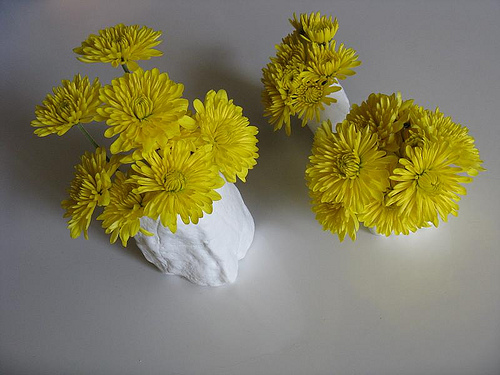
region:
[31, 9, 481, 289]
three vases with yellow bouquets of flowers in each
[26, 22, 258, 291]
largest white vase with yellow flowers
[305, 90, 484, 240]
medium sized white vase with yellow flowers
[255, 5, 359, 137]
smallest white vase with yellow flowers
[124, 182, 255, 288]
white vase for flowers with textured sides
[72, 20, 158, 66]
single yellow flower with a green stem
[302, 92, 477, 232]
several yellow flowers in a bunch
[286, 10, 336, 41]
partially wilted single yellow flower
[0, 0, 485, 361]
gray display table holding three flower vases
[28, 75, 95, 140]
single yellow flower in a larger bunch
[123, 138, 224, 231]
The flower is yellow.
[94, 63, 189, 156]
The flower is yellow.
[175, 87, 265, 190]
The flower is yellow.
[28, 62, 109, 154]
The flower is yellow.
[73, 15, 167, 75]
The flower is yellow.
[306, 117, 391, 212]
The flower is yellow.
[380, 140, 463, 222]
The flower is yellow.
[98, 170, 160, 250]
The flower is yellow.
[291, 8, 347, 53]
The flower is yellow.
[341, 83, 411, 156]
The flower is yellow.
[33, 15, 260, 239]
an arrangement of yellow flowers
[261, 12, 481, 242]
a small group of yellow flowers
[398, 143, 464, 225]
a yellow flower with many petals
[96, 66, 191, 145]
a yellow flower in the center of a bunch of flowers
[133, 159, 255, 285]
a white base that yellow flowers are stuck into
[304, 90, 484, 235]
yellow flowers with many petals spread out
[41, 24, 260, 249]
a grouping of yellow flowers arranged in a base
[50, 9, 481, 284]
two arrangements of yellow flowers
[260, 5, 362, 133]
small bunch of flowers behind another bunch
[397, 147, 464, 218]
yellow flower with a tight center and wide petals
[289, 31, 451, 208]
yellow flower in vase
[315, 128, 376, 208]
yellow pedals of flowers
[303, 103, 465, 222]
four yellow flours in a group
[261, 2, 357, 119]
yellow flowers in a group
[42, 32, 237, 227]
group of yellow flowers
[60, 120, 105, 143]
green stem of flowers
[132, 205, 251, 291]
white container for flowers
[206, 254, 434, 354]
white table in foreground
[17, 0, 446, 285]
three containers with flowers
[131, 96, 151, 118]
yellow and green middle to flower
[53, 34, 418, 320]
two different vases with flowers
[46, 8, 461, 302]
the vases are white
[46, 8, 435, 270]
white vases on white background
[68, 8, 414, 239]
the flowers are yellow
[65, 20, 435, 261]
the flowers are sunflowers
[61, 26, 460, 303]
two different sets of flowers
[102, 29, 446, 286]
there are many petals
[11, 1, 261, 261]
seven flowers in the vase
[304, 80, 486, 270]
six flowers in the vase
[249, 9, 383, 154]
the flowers are squished together